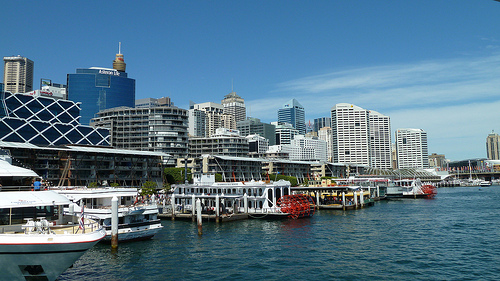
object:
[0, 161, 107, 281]
yacht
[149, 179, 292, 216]
yacht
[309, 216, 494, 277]
river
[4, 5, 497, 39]
skyline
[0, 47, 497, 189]
city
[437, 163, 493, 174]
flag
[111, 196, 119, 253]
post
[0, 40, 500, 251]
building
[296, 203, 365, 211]
pier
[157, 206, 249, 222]
pier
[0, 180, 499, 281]
harbor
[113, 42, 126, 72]
tower